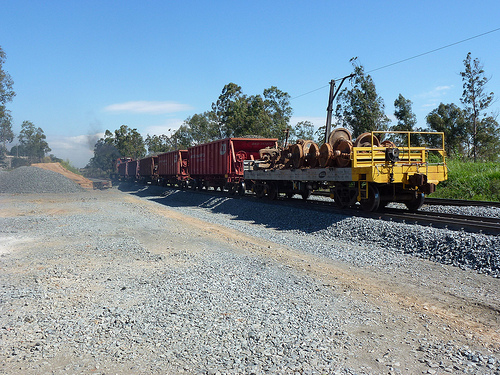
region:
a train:
[131, 74, 258, 271]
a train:
[255, 62, 382, 246]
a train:
[238, 72, 332, 150]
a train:
[237, 104, 395, 308]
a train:
[142, 32, 422, 337]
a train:
[202, 1, 482, 232]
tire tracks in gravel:
[167, 226, 450, 343]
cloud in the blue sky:
[54, 31, 196, 115]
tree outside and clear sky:
[451, 51, 491, 156]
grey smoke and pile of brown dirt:
[43, 96, 119, 201]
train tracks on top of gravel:
[436, 194, 488, 274]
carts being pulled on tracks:
[66, 141, 422, 221]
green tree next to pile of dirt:
[5, 85, 60, 178]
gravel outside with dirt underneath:
[47, 224, 298, 338]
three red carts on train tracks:
[137, 127, 229, 190]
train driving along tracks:
[59, 59, 472, 331]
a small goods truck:
[78, 125, 458, 240]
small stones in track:
[50, 205, 494, 374]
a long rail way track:
[102, 135, 498, 239]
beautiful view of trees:
[23, 88, 489, 193]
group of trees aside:
[1, 57, 492, 374]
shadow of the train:
[234, 190, 328, 240]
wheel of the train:
[337, 185, 389, 207]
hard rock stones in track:
[399, 218, 498, 259]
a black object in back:
[368, 141, 405, 172]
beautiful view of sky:
[60, 10, 499, 136]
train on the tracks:
[100, 107, 467, 232]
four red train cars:
[112, 126, 269, 184]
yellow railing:
[368, 118, 456, 190]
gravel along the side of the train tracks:
[9, 152, 491, 374]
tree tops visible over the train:
[92, 86, 319, 154]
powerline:
[326, 21, 496, 142]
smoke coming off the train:
[60, 119, 130, 172]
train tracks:
[395, 203, 499, 257]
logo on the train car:
[218, 142, 228, 158]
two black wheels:
[330, 183, 377, 210]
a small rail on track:
[91, 134, 447, 228]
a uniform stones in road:
[28, 160, 288, 371]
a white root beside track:
[81, 168, 470, 348]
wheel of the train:
[311, 186, 359, 210]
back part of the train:
[354, 125, 449, 232]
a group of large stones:
[361, 215, 466, 261]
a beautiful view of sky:
[34, 17, 482, 144]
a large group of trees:
[149, 92, 498, 193]